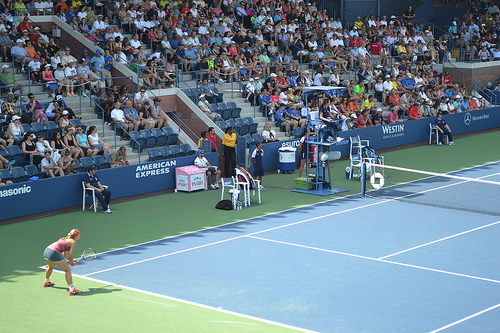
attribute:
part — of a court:
[339, 272, 369, 304]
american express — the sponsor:
[131, 160, 178, 180]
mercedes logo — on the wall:
[463, 108, 473, 129]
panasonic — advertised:
[2, 183, 33, 198]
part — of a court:
[296, 265, 359, 305]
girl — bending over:
[40, 228, 87, 298]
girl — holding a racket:
[39, 224, 98, 295]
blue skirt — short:
[41, 246, 61, 265]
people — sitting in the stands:
[4, 1, 303, 140]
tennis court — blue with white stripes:
[56, 168, 467, 327]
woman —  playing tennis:
[35, 224, 85, 296]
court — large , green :
[2, 124, 496, 329]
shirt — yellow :
[222, 132, 238, 146]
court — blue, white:
[40, 159, 484, 324]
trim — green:
[7, 121, 484, 320]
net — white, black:
[354, 158, 484, 220]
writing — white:
[133, 155, 177, 183]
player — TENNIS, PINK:
[26, 222, 90, 293]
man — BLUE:
[434, 114, 450, 136]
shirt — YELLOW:
[218, 132, 231, 142]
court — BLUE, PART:
[283, 259, 379, 329]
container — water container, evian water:
[179, 167, 209, 196]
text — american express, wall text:
[133, 161, 194, 174]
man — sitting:
[430, 107, 455, 146]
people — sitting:
[17, 15, 456, 130]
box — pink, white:
[172, 164, 206, 194]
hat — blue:
[88, 162, 98, 171]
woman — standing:
[211, 124, 244, 180]